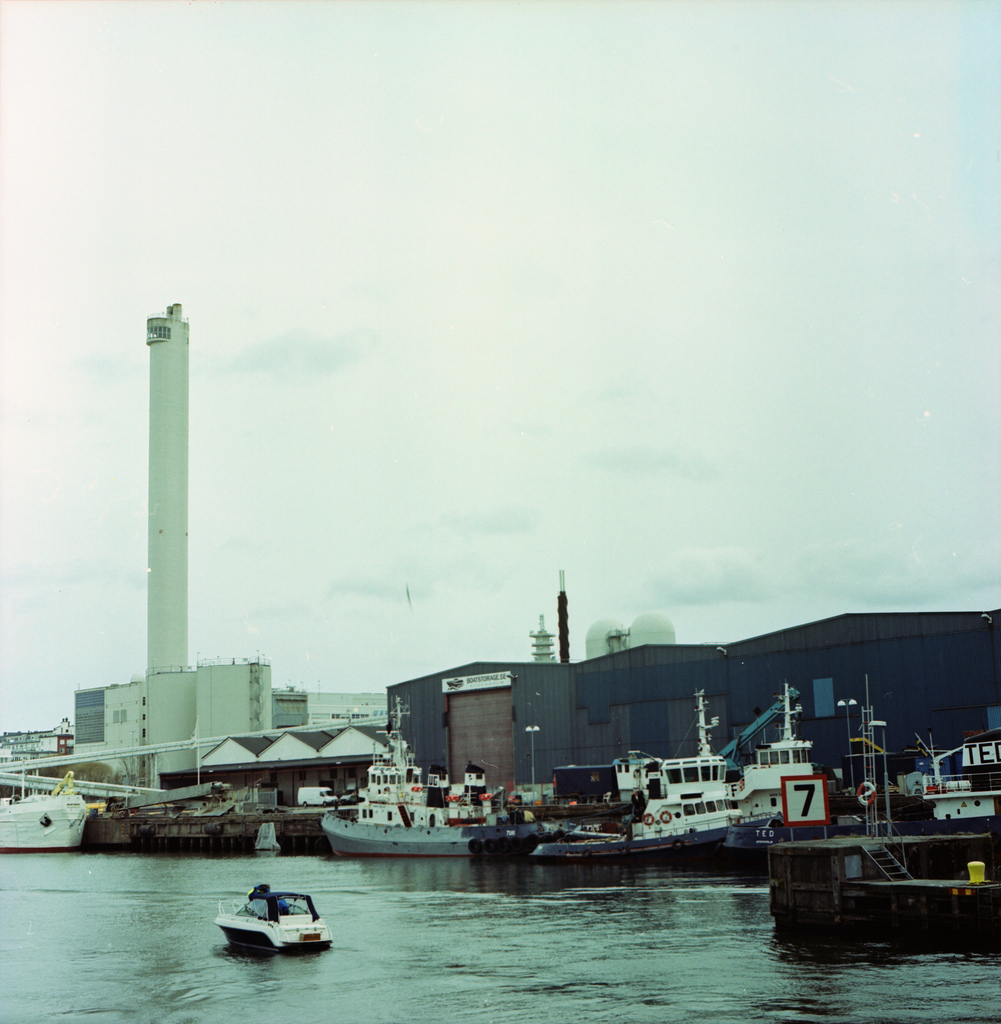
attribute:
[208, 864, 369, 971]
boat — black, small white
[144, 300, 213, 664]
cylinder —  large white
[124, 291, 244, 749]
tower — tall white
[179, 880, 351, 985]
boat — floating, white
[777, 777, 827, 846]
number — black , 7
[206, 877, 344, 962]
tugboat — white 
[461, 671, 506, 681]
letter — t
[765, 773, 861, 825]
sign — Square 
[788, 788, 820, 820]
number — Black , 7 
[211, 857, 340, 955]
boat — Blue , white 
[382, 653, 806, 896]
building — Large door 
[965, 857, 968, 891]
can — Yellow  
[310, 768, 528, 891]
boat — Large   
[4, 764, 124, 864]
van — White 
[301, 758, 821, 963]
ship — Large white